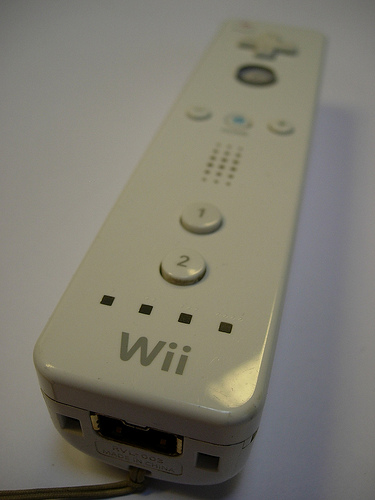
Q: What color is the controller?
A: White.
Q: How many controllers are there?
A: One.